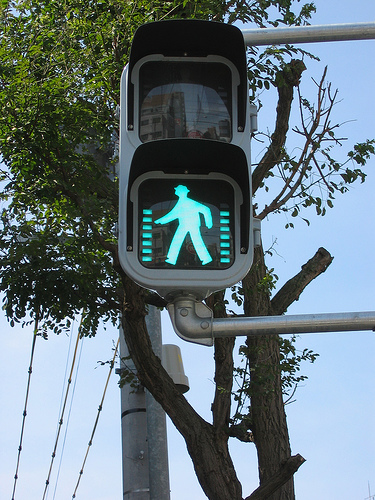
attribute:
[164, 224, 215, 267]
pants — green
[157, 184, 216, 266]
figure — walking, green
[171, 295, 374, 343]
pole — metal, dark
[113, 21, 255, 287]
light — blank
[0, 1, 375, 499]
tree — brown, tall, green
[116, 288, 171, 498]
pole — tall, thick, gray, large, metal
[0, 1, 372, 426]
leaves — green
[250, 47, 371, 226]
branches — small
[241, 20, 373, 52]
pole — metal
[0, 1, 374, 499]
sky — blue, clear, cloudless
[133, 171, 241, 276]
signal — green, black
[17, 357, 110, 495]
wire — barbed, black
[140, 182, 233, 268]
sign — green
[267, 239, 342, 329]
branch — leafless, brown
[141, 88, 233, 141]
city — reflected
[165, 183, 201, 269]
man — green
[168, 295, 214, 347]
joint — metal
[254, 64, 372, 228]
branches — thin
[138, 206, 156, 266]
dashes — green